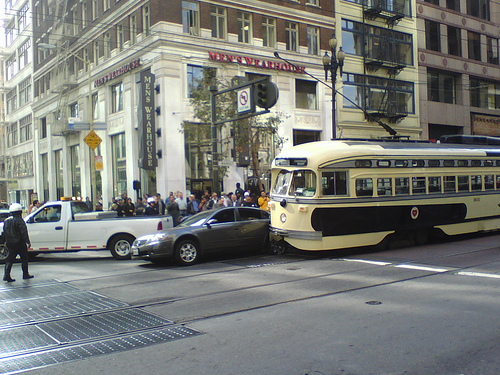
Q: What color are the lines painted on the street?
A: White.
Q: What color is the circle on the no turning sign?
A: Red.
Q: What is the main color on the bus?
A: Yellow.